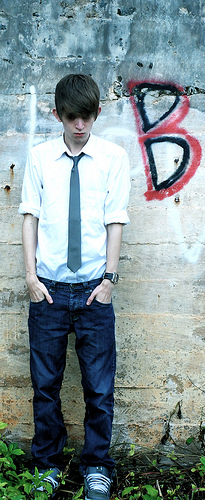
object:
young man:
[19, 74, 130, 500]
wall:
[131, 193, 204, 404]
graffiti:
[127, 80, 202, 200]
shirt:
[19, 132, 130, 283]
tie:
[65, 153, 84, 273]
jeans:
[28, 282, 64, 470]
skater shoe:
[31, 468, 64, 500]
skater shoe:
[81, 465, 111, 500]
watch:
[105, 272, 120, 284]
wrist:
[104, 269, 116, 285]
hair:
[54, 74, 100, 122]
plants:
[23, 465, 53, 499]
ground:
[1, 457, 204, 499]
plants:
[121, 483, 141, 500]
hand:
[25, 279, 54, 304]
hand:
[86, 279, 116, 306]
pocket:
[28, 291, 51, 327]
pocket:
[87, 290, 115, 329]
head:
[54, 75, 99, 146]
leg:
[28, 320, 67, 470]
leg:
[79, 320, 115, 468]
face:
[61, 114, 93, 143]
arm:
[86, 149, 129, 304]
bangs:
[61, 90, 95, 115]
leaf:
[122, 486, 135, 496]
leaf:
[143, 485, 159, 499]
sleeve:
[20, 150, 44, 219]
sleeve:
[103, 143, 131, 226]